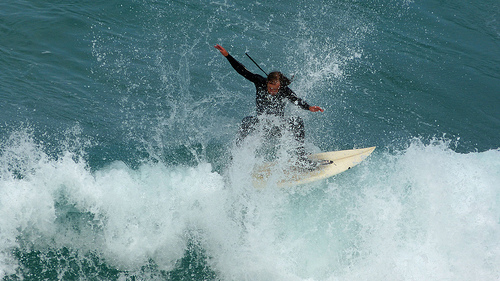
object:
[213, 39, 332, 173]
man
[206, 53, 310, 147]
wet suit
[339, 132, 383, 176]
tip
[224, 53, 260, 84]
arm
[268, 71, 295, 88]
hair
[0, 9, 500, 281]
waves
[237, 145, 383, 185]
surfboard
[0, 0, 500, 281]
water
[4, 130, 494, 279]
foam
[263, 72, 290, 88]
head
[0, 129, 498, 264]
crest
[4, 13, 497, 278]
spray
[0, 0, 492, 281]
ocean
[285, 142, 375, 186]
front end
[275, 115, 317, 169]
legs